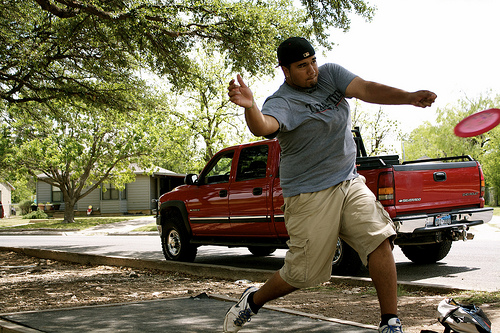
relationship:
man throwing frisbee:
[223, 37, 436, 332] [454, 108, 500, 138]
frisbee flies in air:
[454, 108, 500, 138] [0, 2, 500, 331]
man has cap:
[223, 37, 436, 332] [275, 37, 316, 68]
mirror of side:
[185, 173, 201, 185] [152, 138, 287, 261]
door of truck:
[232, 145, 271, 241] [155, 138, 288, 263]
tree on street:
[0, 71, 204, 229] [1, 232, 165, 260]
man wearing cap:
[223, 37, 436, 332] [275, 37, 316, 68]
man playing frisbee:
[223, 37, 436, 332] [454, 108, 500, 138]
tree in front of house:
[0, 71, 204, 229] [30, 161, 183, 218]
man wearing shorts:
[223, 37, 436, 332] [278, 173, 396, 288]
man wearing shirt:
[223, 37, 436, 332] [261, 64, 358, 197]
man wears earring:
[223, 37, 436, 332] [284, 73, 291, 79]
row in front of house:
[32, 202, 64, 212] [30, 161, 183, 218]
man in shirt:
[223, 37, 436, 332] [261, 64, 358, 197]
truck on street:
[155, 138, 288, 263] [1, 232, 165, 260]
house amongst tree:
[482, 156, 500, 206] [462, 87, 499, 207]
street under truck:
[1, 232, 165, 260] [155, 138, 288, 263]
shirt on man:
[261, 64, 358, 197] [223, 37, 436, 332]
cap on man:
[275, 37, 316, 68] [223, 37, 436, 332]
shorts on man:
[278, 173, 396, 288] [223, 37, 436, 332]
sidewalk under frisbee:
[1, 291, 380, 332] [454, 108, 500, 138]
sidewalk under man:
[1, 291, 380, 332] [223, 37, 436, 332]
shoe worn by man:
[379, 319, 402, 332] [223, 37, 436, 332]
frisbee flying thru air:
[454, 108, 500, 138] [0, 2, 500, 331]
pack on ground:
[435, 292, 499, 332] [2, 206, 499, 332]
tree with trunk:
[0, 71, 204, 229] [60, 193, 80, 224]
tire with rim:
[162, 216, 198, 260] [168, 230, 181, 254]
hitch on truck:
[458, 220, 470, 241] [353, 126, 495, 262]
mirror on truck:
[185, 173, 201, 185] [155, 138, 288, 263]